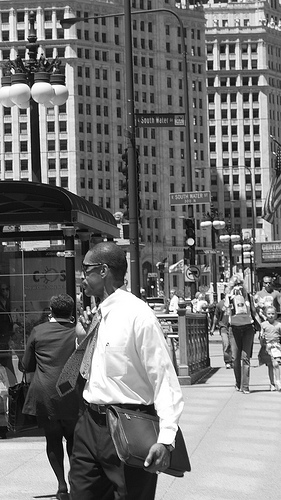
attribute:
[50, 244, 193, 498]
man — turned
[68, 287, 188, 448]
shirt — button down, white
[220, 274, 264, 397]
woman — on sidewalk, walking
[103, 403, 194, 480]
portfolio — black, thick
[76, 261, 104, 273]
glasses — black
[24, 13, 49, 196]
pole — for lights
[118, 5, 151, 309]
pole — black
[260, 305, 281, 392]
girl — wearing dress, little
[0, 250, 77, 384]
window — big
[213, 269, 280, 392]
people — walking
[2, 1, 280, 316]
buildings — big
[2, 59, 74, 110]
lights — round, white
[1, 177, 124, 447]
bus stop — on sidewalk, black, on side street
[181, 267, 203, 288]
sign — a street, no trucks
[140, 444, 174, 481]
hand — man's left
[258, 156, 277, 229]
flag — flying, american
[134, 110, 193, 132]
sign — street name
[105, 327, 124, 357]
pocket — in front of shirt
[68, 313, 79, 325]
earrings — hooped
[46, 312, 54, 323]
earrings — hooped